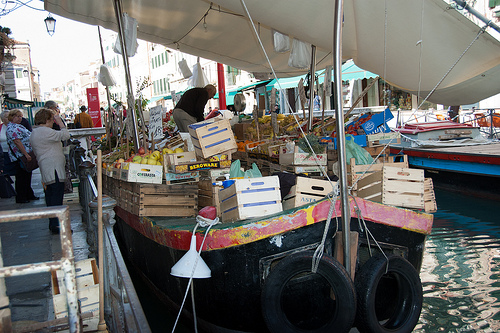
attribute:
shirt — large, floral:
[5, 122, 34, 164]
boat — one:
[81, 133, 434, 330]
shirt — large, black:
[175, 86, 208, 117]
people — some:
[7, 93, 77, 208]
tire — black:
[251, 243, 376, 330]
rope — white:
[305, 180, 354, 237]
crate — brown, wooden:
[208, 165, 309, 234]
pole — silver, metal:
[315, 4, 379, 294]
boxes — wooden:
[148, 124, 309, 206]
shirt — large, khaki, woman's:
[29, 115, 99, 197]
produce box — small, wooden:
[350, 144, 439, 221]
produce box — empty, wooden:
[358, 159, 445, 231]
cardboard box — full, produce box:
[105, 149, 171, 199]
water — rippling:
[433, 234, 481, 330]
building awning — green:
[225, 70, 387, 100]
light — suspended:
[42, 12, 56, 37]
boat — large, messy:
[42, 0, 483, 330]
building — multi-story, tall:
[147, 40, 173, 110]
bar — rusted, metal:
[58, 206, 82, 331]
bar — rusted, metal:
[1, 203, 68, 223]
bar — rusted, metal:
[1, 258, 64, 278]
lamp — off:
[43, 10, 57, 38]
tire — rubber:
[355, 250, 425, 331]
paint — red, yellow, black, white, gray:
[113, 194, 433, 331]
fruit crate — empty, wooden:
[352, 163, 425, 213]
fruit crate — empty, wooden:
[421, 175, 439, 212]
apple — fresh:
[145, 156, 157, 166]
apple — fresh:
[147, 152, 158, 159]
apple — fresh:
[172, 147, 183, 154]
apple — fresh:
[135, 145, 146, 155]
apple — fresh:
[131, 152, 144, 162]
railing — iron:
[74, 137, 158, 329]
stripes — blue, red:
[398, 155, 498, 179]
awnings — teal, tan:
[235, 58, 394, 100]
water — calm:
[424, 212, 499, 322]